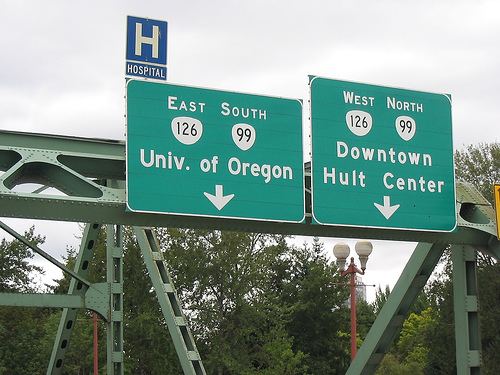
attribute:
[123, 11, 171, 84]
hospital sign — blue, white, freeway sign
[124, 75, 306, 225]
freeway sign — green', highway sign, univ, oregon exit, east route 126 exit, route 99 south exit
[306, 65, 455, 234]
freeway sign — highway sign, hult center exit, downtown eugene exit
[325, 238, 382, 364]
lamp post — red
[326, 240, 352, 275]
lamp — globe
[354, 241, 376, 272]
lamp — globe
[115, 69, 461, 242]
freeway signs — on the highway, in eugene, oregon, like *intra*state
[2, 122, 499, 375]
trestle — minty green, metal, above freeway, fairly uncomplicated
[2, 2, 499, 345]
sky — overcast, *not* blue, grey, cloudy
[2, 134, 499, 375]
trees — leafy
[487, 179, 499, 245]
sign — not featured, edge only, yellow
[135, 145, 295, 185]
university of oregon — noted straight ahead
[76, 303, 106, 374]
lamp post — red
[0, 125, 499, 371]
freeway bridge — trestle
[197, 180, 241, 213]
straight ahead arrow — white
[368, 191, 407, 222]
straight ahead arrow — white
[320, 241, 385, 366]
street lamp — decorative, old-fashioned type, antique copy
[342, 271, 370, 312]
building — very tall, maybe skyscraper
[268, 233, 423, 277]
cloud — large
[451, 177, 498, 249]
corner — mildly faded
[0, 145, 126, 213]
bolts — painted minty green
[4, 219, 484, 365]
supports — two green bridge